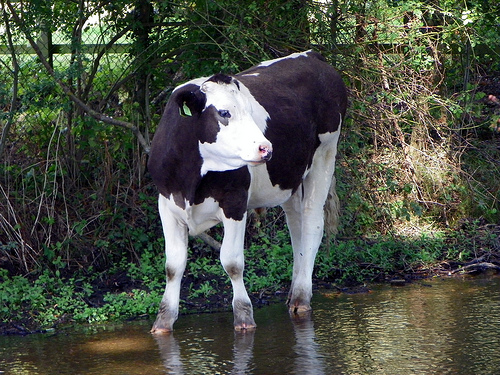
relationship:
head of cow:
[152, 60, 295, 171] [139, 39, 393, 333]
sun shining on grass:
[366, 194, 446, 239] [376, 203, 449, 273]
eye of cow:
[203, 98, 257, 143] [139, 39, 393, 333]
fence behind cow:
[1, 20, 153, 125] [139, 39, 393, 333]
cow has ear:
[139, 39, 393, 333] [158, 81, 208, 132]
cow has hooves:
[139, 39, 393, 333] [147, 320, 268, 370]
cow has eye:
[139, 39, 393, 333] [203, 98, 257, 143]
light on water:
[371, 288, 426, 338] [323, 301, 429, 362]